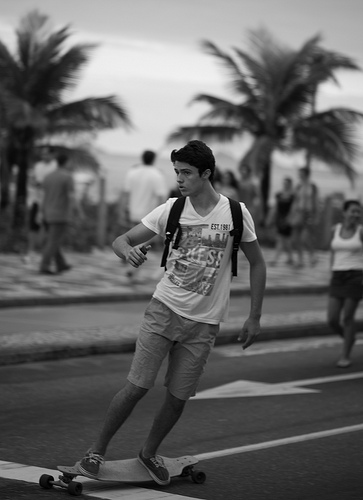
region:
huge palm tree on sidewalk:
[220, 39, 305, 211]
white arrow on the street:
[191, 371, 321, 409]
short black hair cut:
[161, 146, 212, 167]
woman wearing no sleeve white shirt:
[323, 218, 361, 269]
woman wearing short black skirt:
[317, 259, 361, 298]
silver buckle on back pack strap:
[148, 224, 185, 248]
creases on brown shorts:
[130, 301, 219, 371]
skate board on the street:
[35, 451, 223, 480]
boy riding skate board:
[60, 141, 279, 479]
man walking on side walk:
[36, 155, 82, 268]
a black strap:
[226, 196, 244, 276]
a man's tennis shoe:
[135, 449, 173, 486]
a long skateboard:
[37, 445, 207, 499]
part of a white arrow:
[187, 364, 361, 409]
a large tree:
[168, 24, 360, 244]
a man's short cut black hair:
[168, 136, 216, 184]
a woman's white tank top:
[327, 218, 361, 269]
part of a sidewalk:
[0, 282, 360, 364]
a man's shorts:
[127, 295, 218, 403]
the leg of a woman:
[270, 230, 289, 262]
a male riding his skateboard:
[37, 137, 270, 497]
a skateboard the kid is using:
[35, 451, 208, 499]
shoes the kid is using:
[76, 444, 175, 486]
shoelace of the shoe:
[82, 447, 106, 467]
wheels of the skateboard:
[38, 472, 84, 495]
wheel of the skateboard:
[190, 467, 207, 485]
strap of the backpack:
[227, 195, 244, 277]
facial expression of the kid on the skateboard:
[172, 160, 204, 198]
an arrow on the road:
[186, 365, 362, 407]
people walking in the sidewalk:
[24, 142, 325, 276]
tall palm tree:
[198, 35, 355, 223]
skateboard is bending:
[43, 451, 204, 491]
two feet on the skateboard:
[39, 447, 202, 494]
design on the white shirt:
[169, 223, 229, 295]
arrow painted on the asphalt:
[187, 372, 359, 400]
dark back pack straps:
[161, 197, 242, 265]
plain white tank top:
[328, 224, 361, 269]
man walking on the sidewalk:
[37, 154, 81, 274]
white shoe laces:
[149, 455, 163, 468]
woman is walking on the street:
[329, 200, 361, 363]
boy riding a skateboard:
[38, 137, 266, 495]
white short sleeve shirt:
[140, 193, 258, 325]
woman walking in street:
[325, 199, 360, 367]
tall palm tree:
[164, 19, 360, 229]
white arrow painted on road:
[186, 370, 362, 398]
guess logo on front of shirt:
[163, 220, 231, 297]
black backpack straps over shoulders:
[160, 194, 243, 280]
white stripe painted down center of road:
[193, 421, 361, 459]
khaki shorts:
[124, 296, 220, 402]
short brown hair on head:
[170, 139, 214, 198]